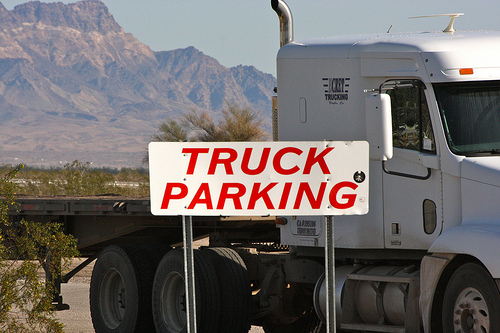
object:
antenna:
[405, 12, 463, 32]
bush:
[0, 163, 82, 333]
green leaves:
[10, 215, 44, 237]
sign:
[148, 140, 371, 216]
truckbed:
[3, 195, 276, 217]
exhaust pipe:
[270, 0, 294, 42]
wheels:
[149, 246, 253, 333]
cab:
[275, 27, 499, 253]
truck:
[0, 0, 498, 330]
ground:
[0, 283, 96, 333]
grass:
[0, 161, 149, 197]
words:
[181, 147, 335, 176]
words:
[159, 181, 358, 210]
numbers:
[296, 219, 301, 227]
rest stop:
[0, 196, 273, 259]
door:
[381, 79, 442, 250]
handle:
[391, 221, 401, 236]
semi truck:
[3, 0, 500, 332]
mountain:
[0, 0, 273, 139]